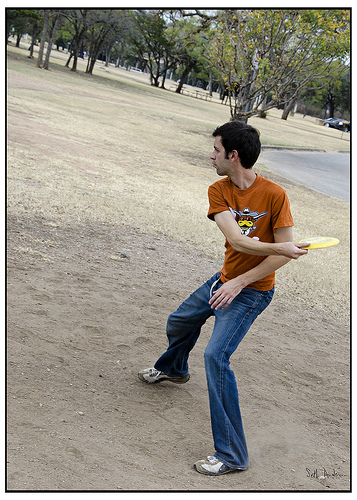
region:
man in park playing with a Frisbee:
[136, 122, 337, 475]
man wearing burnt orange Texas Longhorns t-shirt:
[206, 172, 295, 291]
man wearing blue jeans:
[152, 270, 275, 470]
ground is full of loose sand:
[7, 216, 355, 489]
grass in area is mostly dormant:
[5, 34, 350, 317]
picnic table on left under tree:
[168, 81, 190, 99]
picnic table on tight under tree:
[191, 84, 212, 102]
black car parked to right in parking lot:
[323, 117, 351, 133]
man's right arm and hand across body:
[207, 183, 311, 258]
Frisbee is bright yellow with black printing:
[299, 234, 339, 247]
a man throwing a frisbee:
[136, 121, 340, 476]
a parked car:
[317, 115, 348, 131]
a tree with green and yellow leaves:
[197, 8, 351, 130]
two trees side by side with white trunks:
[33, 9, 72, 71]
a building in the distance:
[119, 48, 180, 82]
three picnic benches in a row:
[165, 83, 213, 103]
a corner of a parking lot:
[249, 145, 351, 207]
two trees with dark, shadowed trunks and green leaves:
[125, 9, 215, 94]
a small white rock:
[78, 410, 84, 417]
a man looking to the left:
[136, 120, 340, 475]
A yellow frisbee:
[295, 236, 338, 248]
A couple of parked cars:
[321, 114, 351, 129]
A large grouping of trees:
[5, 7, 349, 125]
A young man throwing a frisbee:
[142, 123, 338, 470]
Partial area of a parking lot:
[250, 149, 348, 203]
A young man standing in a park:
[136, 122, 310, 473]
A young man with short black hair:
[140, 121, 301, 473]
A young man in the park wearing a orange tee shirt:
[138, 121, 310, 473]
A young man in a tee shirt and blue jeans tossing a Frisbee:
[138, 124, 340, 474]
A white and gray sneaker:
[194, 453, 249, 473]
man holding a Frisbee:
[183, 123, 334, 282]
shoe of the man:
[181, 428, 254, 479]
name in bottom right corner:
[298, 464, 348, 484]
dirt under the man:
[61, 393, 123, 447]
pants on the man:
[196, 337, 268, 433]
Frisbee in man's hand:
[297, 226, 343, 263]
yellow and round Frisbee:
[300, 222, 342, 267]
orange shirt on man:
[200, 169, 305, 269]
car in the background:
[313, 108, 346, 140]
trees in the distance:
[53, 33, 183, 73]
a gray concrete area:
[252, 143, 351, 201]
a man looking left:
[137, 120, 310, 477]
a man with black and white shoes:
[137, 352, 249, 475]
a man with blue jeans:
[153, 271, 275, 471]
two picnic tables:
[165, 81, 210, 100]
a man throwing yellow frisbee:
[293, 232, 341, 250]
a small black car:
[315, 114, 348, 129]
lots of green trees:
[3, 6, 353, 124]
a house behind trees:
[73, 40, 176, 76]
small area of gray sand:
[7, 212, 350, 489]